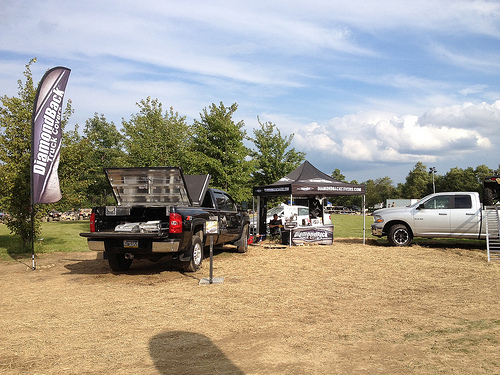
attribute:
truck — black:
[73, 165, 256, 284]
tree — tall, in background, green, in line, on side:
[0, 57, 77, 255]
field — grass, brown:
[1, 237, 497, 374]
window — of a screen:
[419, 196, 452, 213]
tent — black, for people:
[249, 154, 370, 254]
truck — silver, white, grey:
[367, 183, 500, 253]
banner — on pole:
[16, 65, 72, 270]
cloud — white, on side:
[413, 100, 499, 143]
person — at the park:
[266, 210, 286, 242]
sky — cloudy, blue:
[1, 1, 500, 186]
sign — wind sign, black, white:
[197, 218, 223, 286]